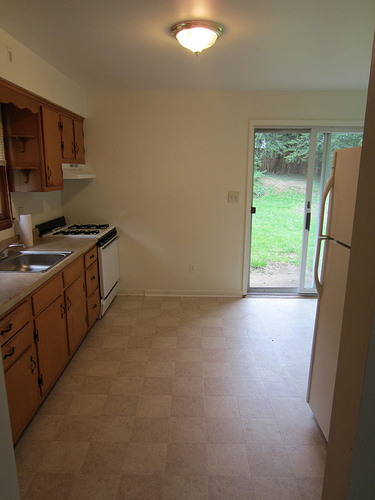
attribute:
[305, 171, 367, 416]
refrigerator — white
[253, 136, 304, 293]
door — screen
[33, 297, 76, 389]
door — wooden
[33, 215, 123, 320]
oven — black, white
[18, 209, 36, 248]
towels — paper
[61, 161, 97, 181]
hood — white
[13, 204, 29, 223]
paper-towel holder — circular, paper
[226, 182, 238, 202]
switch — cream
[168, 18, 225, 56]
light — on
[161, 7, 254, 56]
light — circular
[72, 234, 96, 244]
counter top — beige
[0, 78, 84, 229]
cabinets — brown and black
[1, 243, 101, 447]
cabinets — brown and black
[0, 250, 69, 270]
sink — silver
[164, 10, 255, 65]
light — white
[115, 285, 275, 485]
floor — tan, brown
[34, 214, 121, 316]
range — black, white